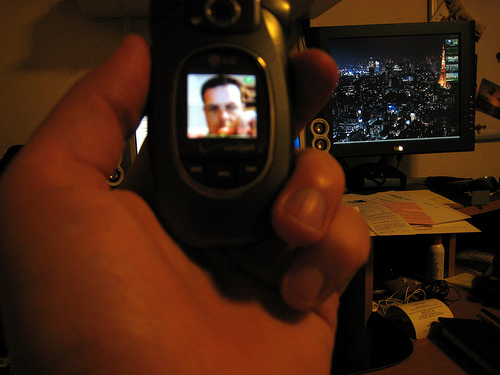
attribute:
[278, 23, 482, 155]
tv — black, flat, on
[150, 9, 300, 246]
cellphone — black, small, closed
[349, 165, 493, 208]
board — grey, small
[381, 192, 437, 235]
paper — pink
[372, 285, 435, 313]
cord — white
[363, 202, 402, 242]
receipt — white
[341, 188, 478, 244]
papers — scattered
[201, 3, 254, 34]
camera — circle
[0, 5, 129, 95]
wall — blank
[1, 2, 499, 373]
room — dark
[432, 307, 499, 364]
book — black